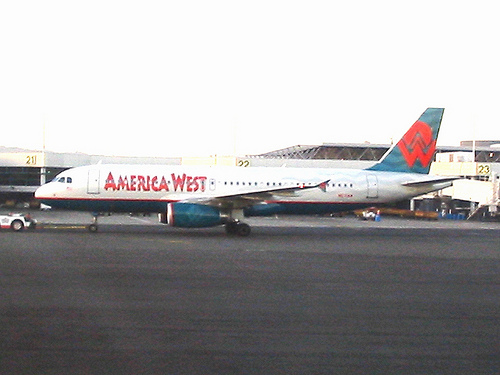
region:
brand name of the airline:
[104, 173, 208, 193]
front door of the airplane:
[87, 167, 103, 196]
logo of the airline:
[397, 123, 437, 168]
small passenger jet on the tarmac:
[32, 104, 460, 236]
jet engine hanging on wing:
[167, 201, 230, 222]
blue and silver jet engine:
[165, 201, 231, 228]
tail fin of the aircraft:
[362, 106, 444, 172]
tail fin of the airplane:
[364, 105, 445, 172]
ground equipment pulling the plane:
[0, 214, 102, 231]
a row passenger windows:
[106, 179, 356, 189]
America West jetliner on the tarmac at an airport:
[21, 99, 496, 236]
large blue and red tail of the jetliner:
[363, 102, 459, 182]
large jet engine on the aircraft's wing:
[157, 199, 235, 231]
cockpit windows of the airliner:
[43, 172, 75, 189]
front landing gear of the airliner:
[86, 217, 106, 237]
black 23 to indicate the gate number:
[476, 162, 492, 175]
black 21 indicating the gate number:
[21, 152, 38, 168]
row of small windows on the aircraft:
[208, 179, 301, 197]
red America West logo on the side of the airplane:
[103, 170, 210, 197]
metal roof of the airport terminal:
[272, 137, 387, 164]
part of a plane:
[357, 183, 367, 188]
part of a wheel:
[173, 190, 191, 215]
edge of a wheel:
[222, 202, 238, 233]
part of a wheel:
[259, 238, 268, 251]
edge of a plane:
[293, 145, 298, 152]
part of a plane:
[288, 279, 297, 304]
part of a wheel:
[195, 227, 203, 259]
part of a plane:
[350, 203, 359, 225]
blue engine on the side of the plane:
[162, 201, 222, 227]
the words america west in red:
[103, 168, 206, 195]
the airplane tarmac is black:
[76, 238, 467, 343]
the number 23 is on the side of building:
[474, 163, 493, 175]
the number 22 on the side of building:
[235, 156, 254, 167]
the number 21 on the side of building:
[22, 154, 41, 168]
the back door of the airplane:
[360, 168, 382, 203]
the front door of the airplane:
[81, 165, 102, 200]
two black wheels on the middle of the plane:
[224, 219, 254, 241]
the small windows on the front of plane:
[49, 173, 75, 185]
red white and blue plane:
[33, 107, 490, 236]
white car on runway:
[1, 211, 33, 233]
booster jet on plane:
[166, 202, 218, 228]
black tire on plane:
[234, 222, 251, 240]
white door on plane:
[87, 169, 100, 196]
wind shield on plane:
[55, 174, 65, 184]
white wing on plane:
[191, 178, 330, 198]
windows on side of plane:
[223, 179, 355, 189]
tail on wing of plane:
[373, 106, 446, 172]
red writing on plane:
[104, 171, 208, 193]